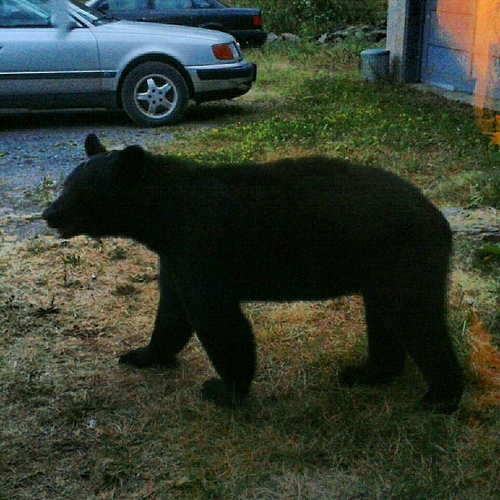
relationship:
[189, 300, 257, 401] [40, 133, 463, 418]
leg on a bear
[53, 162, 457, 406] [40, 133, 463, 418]
side of a bear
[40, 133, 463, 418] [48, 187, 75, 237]
bear has a mouth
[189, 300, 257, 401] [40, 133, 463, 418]
leg of a bear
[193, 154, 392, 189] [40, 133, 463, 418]
back of a bear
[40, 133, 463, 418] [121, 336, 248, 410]
bear has paws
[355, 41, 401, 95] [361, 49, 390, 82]
cone shaped cone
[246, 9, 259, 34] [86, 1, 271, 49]
light on car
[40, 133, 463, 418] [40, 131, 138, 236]
bear has a head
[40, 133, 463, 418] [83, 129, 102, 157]
bear has an ear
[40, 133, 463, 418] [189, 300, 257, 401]
bear has a leg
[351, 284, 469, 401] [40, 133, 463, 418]
legs of a bear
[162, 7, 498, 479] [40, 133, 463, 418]
grass by bear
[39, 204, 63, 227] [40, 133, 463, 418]
nose on bear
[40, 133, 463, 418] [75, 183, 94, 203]
bear has an eye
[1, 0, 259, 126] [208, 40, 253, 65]
car has light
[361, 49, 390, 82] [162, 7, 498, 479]
cone on grass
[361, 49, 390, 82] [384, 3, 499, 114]
cone by wall